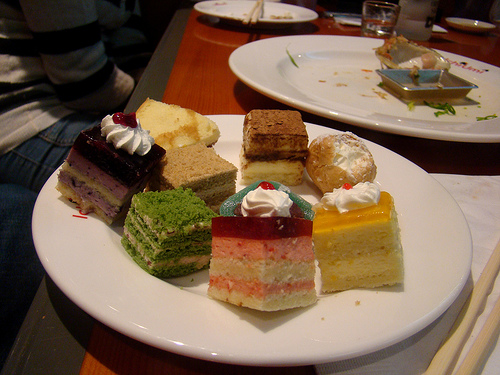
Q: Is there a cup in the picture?
A: Yes, there is a cup.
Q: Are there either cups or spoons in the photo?
A: Yes, there is a cup.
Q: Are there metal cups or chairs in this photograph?
A: Yes, there is a metal cup.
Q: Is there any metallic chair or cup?
A: Yes, there is a metal cup.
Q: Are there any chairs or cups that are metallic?
A: Yes, the cup is metallic.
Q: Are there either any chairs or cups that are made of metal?
A: Yes, the cup is made of metal.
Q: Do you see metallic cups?
A: Yes, there is a metal cup.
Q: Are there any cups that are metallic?
A: Yes, there is a cup that is metallic.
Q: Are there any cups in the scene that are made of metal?
A: Yes, there is a cup that is made of metal.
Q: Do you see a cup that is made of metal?
A: Yes, there is a cup that is made of metal.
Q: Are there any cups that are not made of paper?
A: Yes, there is a cup that is made of metal.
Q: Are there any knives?
A: No, there are no knives.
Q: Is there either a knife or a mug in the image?
A: No, there are no knives or mugs.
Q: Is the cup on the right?
A: Yes, the cup is on the right of the image.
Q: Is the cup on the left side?
A: No, the cup is on the right of the image.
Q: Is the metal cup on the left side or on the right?
A: The cup is on the right of the image.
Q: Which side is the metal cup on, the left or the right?
A: The cup is on the right of the image.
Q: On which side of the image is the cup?
A: The cup is on the right of the image.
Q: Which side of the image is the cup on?
A: The cup is on the right of the image.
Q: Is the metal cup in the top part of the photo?
A: Yes, the cup is in the top of the image.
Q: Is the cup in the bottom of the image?
A: No, the cup is in the top of the image.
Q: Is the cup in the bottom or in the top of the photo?
A: The cup is in the top of the image.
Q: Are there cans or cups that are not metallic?
A: No, there is a cup but it is metallic.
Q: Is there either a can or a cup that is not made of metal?
A: No, there is a cup but it is made of metal.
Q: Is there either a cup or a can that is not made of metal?
A: No, there is a cup but it is made of metal.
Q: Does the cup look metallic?
A: Yes, the cup is metallic.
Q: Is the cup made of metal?
A: Yes, the cup is made of metal.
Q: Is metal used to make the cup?
A: Yes, the cup is made of metal.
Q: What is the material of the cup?
A: The cup is made of metal.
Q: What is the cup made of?
A: The cup is made of metal.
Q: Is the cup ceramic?
A: No, the cup is metallic.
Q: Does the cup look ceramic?
A: No, the cup is metallic.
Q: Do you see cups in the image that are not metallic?
A: No, there is a cup but it is metallic.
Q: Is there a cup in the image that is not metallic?
A: No, there is a cup but it is metallic.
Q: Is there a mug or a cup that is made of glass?
A: No, there is a cup but it is made of metal.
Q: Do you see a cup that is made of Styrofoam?
A: No, there is a cup but it is made of metal.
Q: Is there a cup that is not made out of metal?
A: No, there is a cup but it is made of metal.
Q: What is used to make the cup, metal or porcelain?
A: The cup is made of metal.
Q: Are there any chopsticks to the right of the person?
A: Yes, there are chopsticks to the right of the person.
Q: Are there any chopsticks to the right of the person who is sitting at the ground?
A: Yes, there are chopsticks to the right of the person.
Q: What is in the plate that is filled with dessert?
A: The cakes are in the plate.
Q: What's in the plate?
A: The cakes are in the plate.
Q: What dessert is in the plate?
A: The dessert is cakes.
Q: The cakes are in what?
A: The cakes are in the plate.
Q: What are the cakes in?
A: The cakes are in the plate.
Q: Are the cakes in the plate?
A: Yes, the cakes are in the plate.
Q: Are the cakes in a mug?
A: No, the cakes are in the plate.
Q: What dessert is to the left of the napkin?
A: The dessert is cakes.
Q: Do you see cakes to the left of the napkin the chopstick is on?
A: Yes, there are cakes to the left of the napkin.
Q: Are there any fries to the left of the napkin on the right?
A: No, there are cakes to the left of the napkin.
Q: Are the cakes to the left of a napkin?
A: Yes, the cakes are to the left of a napkin.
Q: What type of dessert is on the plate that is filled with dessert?
A: The dessert is cakes.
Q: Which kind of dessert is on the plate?
A: The dessert is cakes.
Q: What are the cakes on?
A: The cakes are on the plate.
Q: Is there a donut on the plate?
A: No, there are cakes on the plate.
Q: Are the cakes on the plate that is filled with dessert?
A: Yes, the cakes are on the plate.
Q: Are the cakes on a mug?
A: No, the cakes are on the plate.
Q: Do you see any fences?
A: No, there are no fences.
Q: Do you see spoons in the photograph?
A: No, there are no spoons.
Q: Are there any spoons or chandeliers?
A: No, there are no spoons or chandeliers.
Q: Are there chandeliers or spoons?
A: No, there are no spoons or chandeliers.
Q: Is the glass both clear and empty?
A: Yes, the glass is clear and empty.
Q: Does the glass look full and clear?
A: No, the glass is clear but empty.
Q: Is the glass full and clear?
A: No, the glass is clear but empty.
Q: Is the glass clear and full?
A: No, the glass is clear but empty.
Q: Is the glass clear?
A: Yes, the glass is clear.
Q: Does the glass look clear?
A: Yes, the glass is clear.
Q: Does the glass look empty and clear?
A: Yes, the glass is empty and clear.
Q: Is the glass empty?
A: Yes, the glass is empty.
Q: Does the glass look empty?
A: Yes, the glass is empty.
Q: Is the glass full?
A: No, the glass is empty.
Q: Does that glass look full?
A: No, the glass is empty.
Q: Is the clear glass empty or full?
A: The glass is empty.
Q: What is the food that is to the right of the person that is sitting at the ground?
A: The food is a dessert.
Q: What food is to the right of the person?
A: The food is a dessert.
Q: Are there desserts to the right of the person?
A: Yes, there is a dessert to the right of the person.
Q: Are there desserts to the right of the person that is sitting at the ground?
A: Yes, there is a dessert to the right of the person.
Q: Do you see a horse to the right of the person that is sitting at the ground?
A: No, there is a dessert to the right of the person.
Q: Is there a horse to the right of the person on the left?
A: No, there is a dessert to the right of the person.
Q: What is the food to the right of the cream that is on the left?
A: The food is a dessert.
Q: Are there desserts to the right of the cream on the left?
A: Yes, there is a dessert to the right of the cream.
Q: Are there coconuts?
A: No, there are no coconuts.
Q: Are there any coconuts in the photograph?
A: No, there are no coconuts.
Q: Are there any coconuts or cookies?
A: No, there are no coconuts or cookies.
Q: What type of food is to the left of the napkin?
A: The food is a dessert.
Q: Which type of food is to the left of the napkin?
A: The food is a dessert.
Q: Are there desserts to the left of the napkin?
A: Yes, there is a dessert to the left of the napkin.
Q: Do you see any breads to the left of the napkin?
A: No, there is a dessert to the left of the napkin.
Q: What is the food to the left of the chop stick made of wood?
A: The food is a dessert.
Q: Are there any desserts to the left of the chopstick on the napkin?
A: Yes, there is a dessert to the left of the chop stick.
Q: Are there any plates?
A: Yes, there is a plate.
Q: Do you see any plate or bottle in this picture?
A: Yes, there is a plate.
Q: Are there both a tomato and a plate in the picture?
A: No, there is a plate but no tomatoes.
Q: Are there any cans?
A: No, there are no cans.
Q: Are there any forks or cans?
A: No, there are no cans or forks.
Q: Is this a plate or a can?
A: This is a plate.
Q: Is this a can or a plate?
A: This is a plate.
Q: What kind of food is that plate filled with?
A: The plate is filled with dessert.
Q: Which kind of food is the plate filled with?
A: The plate is filled with dessert.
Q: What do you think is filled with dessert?
A: The plate is filled with dessert.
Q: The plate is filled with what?
A: The plate is filled with dessert.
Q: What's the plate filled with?
A: The plate is filled with dessert.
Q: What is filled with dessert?
A: The plate is filled with dessert.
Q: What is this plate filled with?
A: The plate is filled with dessert.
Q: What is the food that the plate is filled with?
A: The food is a dessert.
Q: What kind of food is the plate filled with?
A: The plate is filled with dessert.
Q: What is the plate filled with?
A: The plate is filled with dessert.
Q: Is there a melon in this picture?
A: No, there are no melons.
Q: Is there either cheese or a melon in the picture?
A: No, there are no melons or cheese.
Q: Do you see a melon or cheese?
A: No, there are no melons or cheese.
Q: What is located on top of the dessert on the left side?
A: The cream is on top of the dessert.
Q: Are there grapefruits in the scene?
A: No, there are no grapefruits.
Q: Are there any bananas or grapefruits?
A: No, there are no grapefruits or bananas.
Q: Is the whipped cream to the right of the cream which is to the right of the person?
A: Yes, the whipped cream is to the right of the cream.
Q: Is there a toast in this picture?
A: No, there are no toasts.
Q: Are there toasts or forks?
A: No, there are no toasts or forks.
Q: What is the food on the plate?
A: The food is a dessert.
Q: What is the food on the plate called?
A: The food is a dessert.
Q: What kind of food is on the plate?
A: The food is a dessert.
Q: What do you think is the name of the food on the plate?
A: The food is a dessert.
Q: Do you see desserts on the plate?
A: Yes, there is a dessert on the plate.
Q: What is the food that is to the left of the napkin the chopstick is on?
A: The food is a dessert.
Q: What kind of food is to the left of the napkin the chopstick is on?
A: The food is a dessert.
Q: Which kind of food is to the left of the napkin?
A: The food is a dessert.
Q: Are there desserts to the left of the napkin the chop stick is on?
A: Yes, there is a dessert to the left of the napkin.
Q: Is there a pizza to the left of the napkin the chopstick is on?
A: No, there is a dessert to the left of the napkin.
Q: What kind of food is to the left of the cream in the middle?
A: The food is a dessert.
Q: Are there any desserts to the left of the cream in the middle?
A: Yes, there is a dessert to the left of the cream.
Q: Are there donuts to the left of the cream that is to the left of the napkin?
A: No, there is a dessert to the left of the cream.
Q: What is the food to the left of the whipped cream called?
A: The food is a dessert.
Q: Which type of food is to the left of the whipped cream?
A: The food is a dessert.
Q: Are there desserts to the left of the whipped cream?
A: Yes, there is a dessert to the left of the whipped cream.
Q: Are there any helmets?
A: No, there are no helmets.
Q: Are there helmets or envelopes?
A: No, there are no helmets or envelopes.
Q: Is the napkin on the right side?
A: Yes, the napkin is on the right of the image.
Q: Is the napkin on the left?
A: No, the napkin is on the right of the image.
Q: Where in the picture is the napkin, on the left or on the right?
A: The napkin is on the right of the image.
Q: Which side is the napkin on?
A: The napkin is on the right of the image.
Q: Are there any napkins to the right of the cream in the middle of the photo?
A: Yes, there is a napkin to the right of the cream.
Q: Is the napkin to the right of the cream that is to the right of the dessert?
A: Yes, the napkin is to the right of the cream.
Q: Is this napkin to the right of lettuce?
A: No, the napkin is to the right of the cream.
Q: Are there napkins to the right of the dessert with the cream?
A: Yes, there is a napkin to the right of the dessert.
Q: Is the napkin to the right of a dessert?
A: Yes, the napkin is to the right of a dessert.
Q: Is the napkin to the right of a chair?
A: No, the napkin is to the right of a dessert.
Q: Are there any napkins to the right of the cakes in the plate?
A: Yes, there is a napkin to the right of the cakes.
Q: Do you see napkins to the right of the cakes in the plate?
A: Yes, there is a napkin to the right of the cakes.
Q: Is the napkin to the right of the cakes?
A: Yes, the napkin is to the right of the cakes.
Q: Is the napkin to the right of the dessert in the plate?
A: Yes, the napkin is to the right of the cakes.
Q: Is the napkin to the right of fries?
A: No, the napkin is to the right of the cakes.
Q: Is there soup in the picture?
A: No, there is no soup.